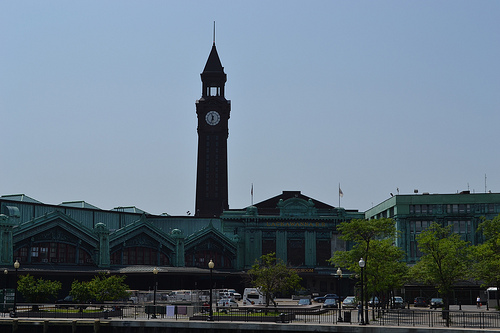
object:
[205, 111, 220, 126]
clock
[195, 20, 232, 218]
tower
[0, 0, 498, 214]
sky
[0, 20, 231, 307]
buildings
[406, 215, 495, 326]
trees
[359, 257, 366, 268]
lamp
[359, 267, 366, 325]
post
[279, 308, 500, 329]
railing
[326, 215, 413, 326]
trees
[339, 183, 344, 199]
flag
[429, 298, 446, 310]
car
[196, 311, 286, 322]
grass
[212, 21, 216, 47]
lightning rod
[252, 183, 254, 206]
pole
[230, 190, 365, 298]
building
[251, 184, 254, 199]
flag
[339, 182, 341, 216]
flag pole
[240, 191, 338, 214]
roof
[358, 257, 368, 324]
lamp post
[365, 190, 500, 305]
buiding